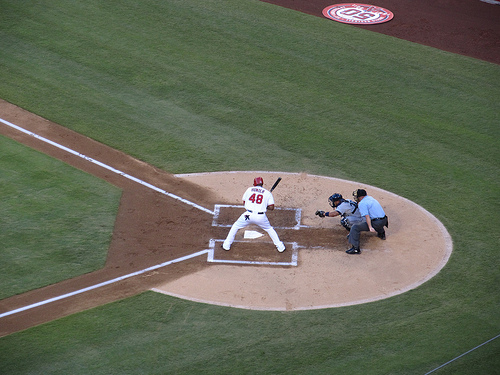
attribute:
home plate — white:
[241, 226, 265, 244]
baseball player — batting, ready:
[217, 172, 289, 254]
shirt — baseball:
[240, 185, 275, 214]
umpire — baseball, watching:
[346, 188, 391, 256]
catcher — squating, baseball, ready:
[312, 194, 365, 234]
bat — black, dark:
[269, 178, 282, 194]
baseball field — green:
[2, 2, 499, 374]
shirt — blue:
[356, 195, 385, 223]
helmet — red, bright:
[252, 176, 265, 187]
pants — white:
[225, 212, 286, 252]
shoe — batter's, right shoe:
[220, 242, 231, 254]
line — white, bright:
[1, 118, 215, 216]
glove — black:
[243, 213, 251, 222]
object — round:
[321, 2, 394, 27]